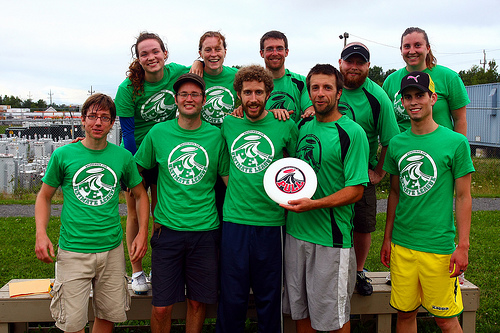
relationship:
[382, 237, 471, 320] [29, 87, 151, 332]
shorts on man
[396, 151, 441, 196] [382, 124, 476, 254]
symbol in green shirt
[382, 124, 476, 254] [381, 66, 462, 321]
green shirt worn by man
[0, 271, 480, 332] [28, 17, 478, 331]
bench behind people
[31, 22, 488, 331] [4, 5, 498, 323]
frisbee team in picture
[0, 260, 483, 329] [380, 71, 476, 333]
bench behind guy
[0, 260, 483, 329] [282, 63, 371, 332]
bench behind guy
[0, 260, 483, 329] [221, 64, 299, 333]
bench behind man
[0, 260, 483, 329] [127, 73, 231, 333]
bench behind man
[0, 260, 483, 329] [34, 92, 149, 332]
bench behind man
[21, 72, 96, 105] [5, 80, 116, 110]
power lines seen distant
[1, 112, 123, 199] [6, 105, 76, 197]
chain in fencing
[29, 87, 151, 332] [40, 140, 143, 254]
man wears green shirt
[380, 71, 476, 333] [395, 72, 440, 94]
guy wears cap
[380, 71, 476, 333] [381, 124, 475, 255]
guy wears green shirt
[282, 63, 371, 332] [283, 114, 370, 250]
guy wears green shirt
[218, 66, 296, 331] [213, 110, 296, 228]
man wears green shirt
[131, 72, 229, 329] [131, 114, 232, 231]
man wears green shirt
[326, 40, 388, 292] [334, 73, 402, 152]
man wears green shirt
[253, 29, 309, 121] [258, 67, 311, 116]
man wears green shirt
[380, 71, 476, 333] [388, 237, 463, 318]
guy wears shorts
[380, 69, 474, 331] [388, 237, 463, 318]
guy wearing shorts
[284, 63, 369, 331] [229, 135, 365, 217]
guy holding frisbee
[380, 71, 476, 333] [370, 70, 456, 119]
guy wearing glasses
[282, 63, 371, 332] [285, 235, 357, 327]
guy wearing shorts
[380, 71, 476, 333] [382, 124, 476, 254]
guy wearing green shirt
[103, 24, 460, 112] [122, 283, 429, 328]
back row standing on bench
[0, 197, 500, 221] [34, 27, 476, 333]
trail behind frisbee team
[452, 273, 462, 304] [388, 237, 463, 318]
bolt on shorts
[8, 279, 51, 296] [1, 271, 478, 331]
paper on bench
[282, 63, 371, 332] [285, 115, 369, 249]
guy wearing green shirt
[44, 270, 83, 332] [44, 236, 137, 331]
pocket on shorts